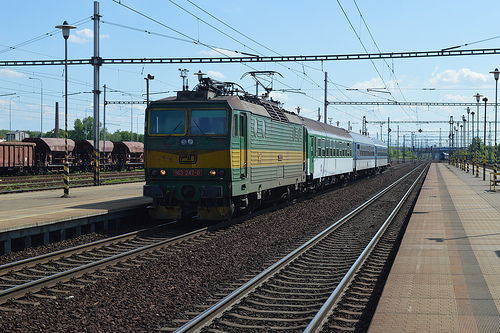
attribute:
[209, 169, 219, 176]
light — yellow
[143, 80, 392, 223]
train — green, traveling, running, approaching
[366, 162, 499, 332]
platform — empty